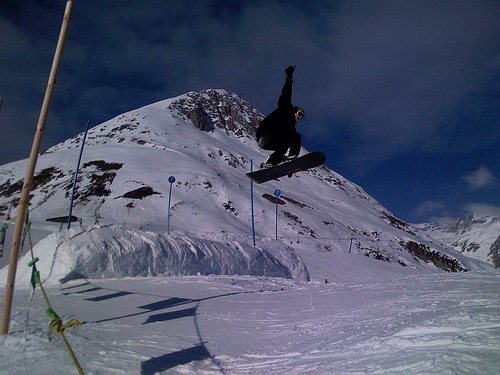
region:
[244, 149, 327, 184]
a snowboard under a man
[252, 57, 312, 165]
a snowboarder in the air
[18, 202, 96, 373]
a rope tied to a pole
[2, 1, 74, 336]
a tall brown pole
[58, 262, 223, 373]
the shadow of flags on the snow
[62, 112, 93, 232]
a blue post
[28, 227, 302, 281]
a snow drift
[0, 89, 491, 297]
a snow covered mountain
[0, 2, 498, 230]
a cloudy blue sky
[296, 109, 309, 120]
sunglasses on a snowboarder's face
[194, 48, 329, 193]
airborne snow boarder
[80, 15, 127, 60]
white clouds in blue sky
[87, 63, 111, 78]
white clouds in blue sky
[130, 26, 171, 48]
white clouds in blue sky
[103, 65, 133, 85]
white clouds in blue sky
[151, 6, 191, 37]
white clouds in blue sky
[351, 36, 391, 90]
white clouds in blue sky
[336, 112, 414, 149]
white clouds in blue sky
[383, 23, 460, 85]
white clouds in blue sky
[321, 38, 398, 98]
white clouds in blue sky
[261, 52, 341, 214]
man doing tricks on snowboard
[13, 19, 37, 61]
white clouds in blue sky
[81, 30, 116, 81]
white clouds in blue sky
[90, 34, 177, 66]
white clouds in blue sky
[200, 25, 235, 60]
white clouds in blue sky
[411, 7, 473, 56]
white clouds in blue sky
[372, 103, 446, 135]
white clouds in blue sky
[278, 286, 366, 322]
white snow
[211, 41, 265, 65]
white clouds in blue sky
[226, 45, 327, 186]
snow boarder in the air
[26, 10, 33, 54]
white clouds in blue sky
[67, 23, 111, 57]
white clouds in blue sky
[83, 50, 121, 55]
white clouds in blue sky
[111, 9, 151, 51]
white clouds in blue sky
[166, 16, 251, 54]
white clouds in blue sky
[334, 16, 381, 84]
white clouds in blue sky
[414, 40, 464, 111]
white clouds in blue sky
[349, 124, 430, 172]
white clouds in blue sky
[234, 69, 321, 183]
snow boarder in air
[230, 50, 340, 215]
snow boarder doing trick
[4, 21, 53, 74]
white clouds in blue sky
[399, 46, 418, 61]
white clouds in blue sky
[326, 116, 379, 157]
white clouds in blue sky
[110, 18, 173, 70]
white clouds in blue sky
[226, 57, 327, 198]
snow boarder wearing black outfit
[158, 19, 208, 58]
white clouds in blue sky